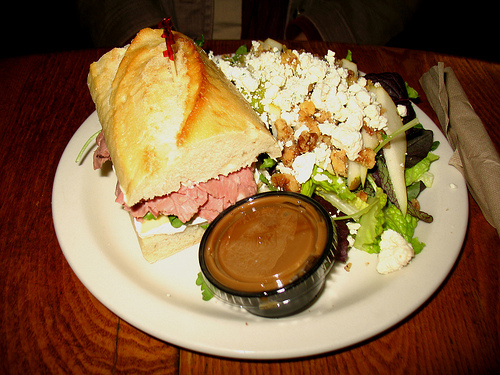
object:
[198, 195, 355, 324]
container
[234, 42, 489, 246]
salad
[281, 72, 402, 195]
cheese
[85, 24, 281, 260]
sandwich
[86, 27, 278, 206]
bun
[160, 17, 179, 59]
tip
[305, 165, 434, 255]
green food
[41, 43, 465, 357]
dish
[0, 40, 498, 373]
brown table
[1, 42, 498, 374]
table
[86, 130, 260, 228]
meat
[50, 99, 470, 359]
plate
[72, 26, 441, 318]
food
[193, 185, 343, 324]
gravy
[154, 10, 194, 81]
toothpick